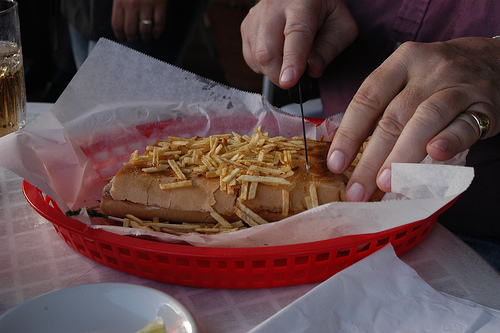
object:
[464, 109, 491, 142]
ring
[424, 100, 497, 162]
finger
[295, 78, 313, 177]
knife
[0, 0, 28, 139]
glass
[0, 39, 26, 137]
liquid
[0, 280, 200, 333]
bowl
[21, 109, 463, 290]
basket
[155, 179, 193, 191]
fries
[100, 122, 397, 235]
food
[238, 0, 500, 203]
person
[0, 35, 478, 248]
paper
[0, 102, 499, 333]
table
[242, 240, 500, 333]
napkin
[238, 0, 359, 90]
fingers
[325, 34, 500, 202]
hand